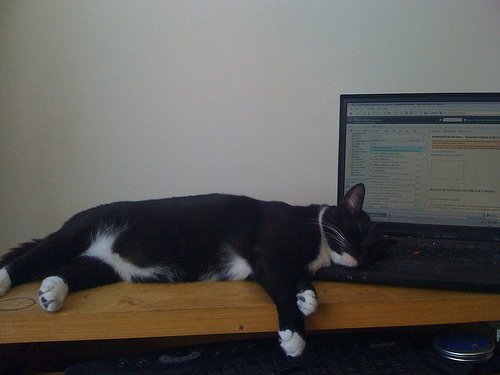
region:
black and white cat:
[1, 181, 400, 358]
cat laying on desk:
[1, 181, 374, 357]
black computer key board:
[51, 336, 442, 374]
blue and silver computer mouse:
[436, 329, 498, 365]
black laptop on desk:
[317, 96, 498, 294]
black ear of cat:
[345, 182, 365, 214]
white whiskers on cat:
[312, 217, 349, 254]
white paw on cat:
[276, 329, 307, 360]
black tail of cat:
[1, 231, 48, 266]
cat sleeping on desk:
[1, 180, 397, 359]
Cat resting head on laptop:
[303, 165, 495, 308]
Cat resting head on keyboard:
[301, 176, 465, 293]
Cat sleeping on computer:
[290, 170, 480, 303]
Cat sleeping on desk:
[1, 179, 388, 357]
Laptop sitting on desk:
[327, 85, 498, 350]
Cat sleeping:
[14, 174, 406, 361]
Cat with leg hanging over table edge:
[1, 187, 398, 371]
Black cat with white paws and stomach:
[1, 180, 400, 372]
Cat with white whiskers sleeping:
[274, 170, 407, 317]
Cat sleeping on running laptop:
[290, 88, 498, 336]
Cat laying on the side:
[1, 182, 394, 359]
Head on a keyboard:
[296, 167, 498, 289]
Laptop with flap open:
[312, 84, 499, 301]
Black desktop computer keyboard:
[47, 319, 498, 374]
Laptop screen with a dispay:
[332, 89, 499, 230]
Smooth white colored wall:
[1, 2, 499, 263]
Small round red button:
[408, 245, 424, 259]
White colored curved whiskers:
[303, 214, 356, 254]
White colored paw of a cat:
[276, 325, 309, 361]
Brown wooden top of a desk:
[0, 279, 499, 354]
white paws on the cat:
[279, 285, 317, 354]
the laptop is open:
[320, 94, 498, 280]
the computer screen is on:
[343, 100, 498, 217]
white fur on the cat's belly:
[87, 228, 165, 280]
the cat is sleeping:
[4, 183, 374, 355]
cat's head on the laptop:
[301, 182, 386, 294]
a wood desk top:
[1, 269, 486, 341]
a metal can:
[428, 333, 495, 362]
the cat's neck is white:
[308, 204, 335, 269]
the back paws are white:
[3, 263, 67, 309]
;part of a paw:
[278, 277, 306, 326]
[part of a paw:
[295, 300, 307, 330]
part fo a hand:
[263, 254, 274, 294]